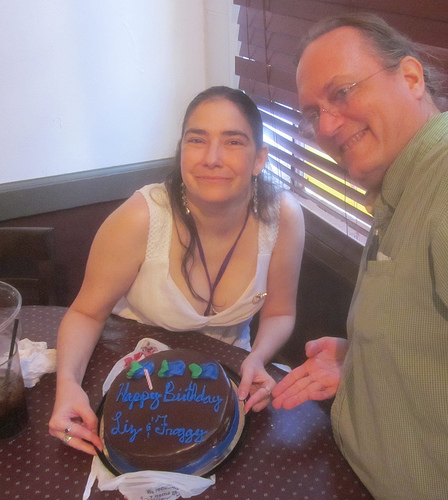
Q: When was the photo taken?
A: Daytime.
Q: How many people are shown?
A: Two.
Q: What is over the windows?
A: Blinds.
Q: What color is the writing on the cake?
A: Blue.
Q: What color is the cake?
A: Brown.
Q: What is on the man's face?
A: Glasses.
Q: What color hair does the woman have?
A: Black.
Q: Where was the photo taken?
A: At woman's birthday party.